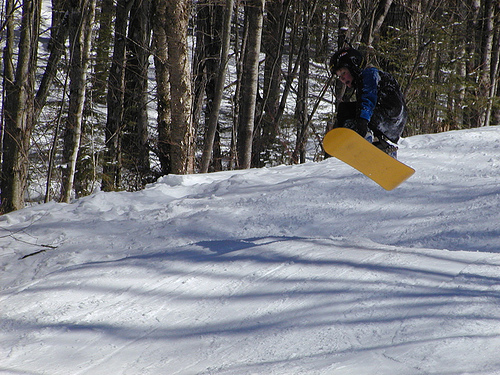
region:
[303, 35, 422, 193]
snowboarder in the air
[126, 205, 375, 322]
snowy slope for riding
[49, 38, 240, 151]
Brown bare winter trees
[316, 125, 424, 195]
Yellow snowboard under kid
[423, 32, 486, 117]
Green pine trees behind kid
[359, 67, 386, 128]
Blue sleeve of coat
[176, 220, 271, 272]
shadow of trees on snow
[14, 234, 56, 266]
sticks laying on the snow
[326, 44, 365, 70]
helmet on head for safety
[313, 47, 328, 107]
snow on the ground between trees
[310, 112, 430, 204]
a yellow snowboard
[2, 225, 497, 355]
the shadow of a tree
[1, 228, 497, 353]
the shadows of tree branches on the snow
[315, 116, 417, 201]
the snowboard is yellow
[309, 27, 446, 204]
this kid is doing a jump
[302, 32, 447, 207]
a boy is riding a snowboard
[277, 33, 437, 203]
he is in midair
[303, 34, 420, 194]
he is jumping with his yellow snowboard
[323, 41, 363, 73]
this is a helmet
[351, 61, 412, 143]
his jacket is black and blue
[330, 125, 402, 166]
he's on the board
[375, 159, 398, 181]
the board is yellow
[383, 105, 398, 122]
the coat is black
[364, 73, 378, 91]
the coat is blue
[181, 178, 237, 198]
the snow is clumpy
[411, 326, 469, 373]
the snow is white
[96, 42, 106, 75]
the tree has moss on it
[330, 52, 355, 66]
the helmet is black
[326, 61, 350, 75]
he's wearing a helmet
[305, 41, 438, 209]
he is in the air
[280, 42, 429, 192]
a snowboarder leaping in the air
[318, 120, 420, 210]
a snowboard that has left the ground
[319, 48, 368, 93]
a black snowboarding helmet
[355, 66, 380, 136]
the arm of a snowboarder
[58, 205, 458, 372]
a snow hill for jumping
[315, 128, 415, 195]
the yellow underside of a snowboard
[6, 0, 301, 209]
trees along the side of the slope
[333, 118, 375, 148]
the boot of the snowboarder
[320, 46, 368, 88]
the head of the snowboarder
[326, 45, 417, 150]
the body of the snowboarder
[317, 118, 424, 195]
A yellow snow board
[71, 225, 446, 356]
White snow on the ground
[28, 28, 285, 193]
Trees with no leaves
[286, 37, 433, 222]
A snow boarder on his snow board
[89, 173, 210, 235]
A pile of snow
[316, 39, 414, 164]
A snow boarder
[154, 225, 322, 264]
Shadows on the snow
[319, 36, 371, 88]
A snow boarder's helmet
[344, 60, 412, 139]
A blue jacket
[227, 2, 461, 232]
A snow boarder in the air